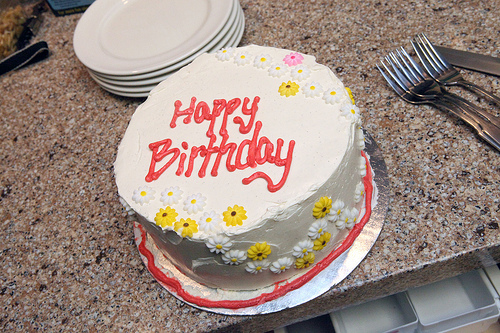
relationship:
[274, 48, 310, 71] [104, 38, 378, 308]
pink flower on cake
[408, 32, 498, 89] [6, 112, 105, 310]
knife on countertop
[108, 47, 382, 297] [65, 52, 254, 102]
birthday cake next to plates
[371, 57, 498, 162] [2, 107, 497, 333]
fork on countertop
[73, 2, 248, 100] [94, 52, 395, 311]
"plates stacked behind cake